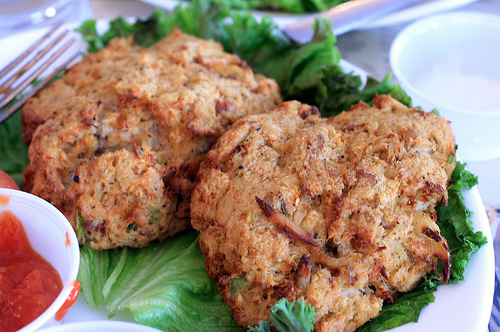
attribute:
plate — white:
[439, 274, 477, 330]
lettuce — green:
[13, 15, 477, 330]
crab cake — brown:
[190, 91, 457, 330]